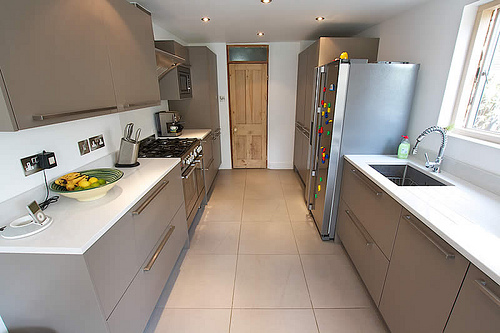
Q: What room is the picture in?
A: It is at the kitchen.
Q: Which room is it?
A: It is a kitchen.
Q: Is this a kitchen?
A: Yes, it is a kitchen.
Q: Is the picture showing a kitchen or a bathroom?
A: It is showing a kitchen.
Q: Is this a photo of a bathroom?
A: No, the picture is showing a kitchen.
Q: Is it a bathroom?
A: No, it is a kitchen.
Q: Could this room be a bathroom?
A: No, it is a kitchen.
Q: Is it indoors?
A: Yes, it is indoors.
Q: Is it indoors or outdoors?
A: It is indoors.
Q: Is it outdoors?
A: No, it is indoors.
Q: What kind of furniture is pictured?
A: The furniture is a drawer.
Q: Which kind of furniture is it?
A: The piece of furniture is a drawer.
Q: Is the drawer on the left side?
A: Yes, the drawer is on the left of the image.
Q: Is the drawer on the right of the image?
A: No, the drawer is on the left of the image.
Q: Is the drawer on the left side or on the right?
A: The drawer is on the left of the image.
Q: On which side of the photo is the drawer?
A: The drawer is on the left of the image.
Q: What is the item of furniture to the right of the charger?
A: The piece of furniture is a drawer.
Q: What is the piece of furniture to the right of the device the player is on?
A: The piece of furniture is a drawer.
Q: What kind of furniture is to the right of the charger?
A: The piece of furniture is a drawer.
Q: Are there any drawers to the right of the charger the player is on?
A: Yes, there is a drawer to the right of the charger.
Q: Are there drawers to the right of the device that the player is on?
A: Yes, there is a drawer to the right of the charger.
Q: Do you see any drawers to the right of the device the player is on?
A: Yes, there is a drawer to the right of the charger.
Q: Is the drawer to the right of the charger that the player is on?
A: Yes, the drawer is to the right of the charger.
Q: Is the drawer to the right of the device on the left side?
A: Yes, the drawer is to the right of the charger.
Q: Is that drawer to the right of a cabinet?
A: No, the drawer is to the right of the charger.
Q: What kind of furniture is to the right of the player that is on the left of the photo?
A: The piece of furniture is a drawer.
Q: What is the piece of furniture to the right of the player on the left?
A: The piece of furniture is a drawer.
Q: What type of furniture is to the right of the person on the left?
A: The piece of furniture is a drawer.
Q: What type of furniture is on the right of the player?
A: The piece of furniture is a drawer.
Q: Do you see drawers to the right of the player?
A: Yes, there is a drawer to the right of the player.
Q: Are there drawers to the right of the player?
A: Yes, there is a drawer to the right of the player.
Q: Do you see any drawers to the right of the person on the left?
A: Yes, there is a drawer to the right of the player.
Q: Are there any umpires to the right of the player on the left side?
A: No, there is a drawer to the right of the player.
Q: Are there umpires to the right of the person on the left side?
A: No, there is a drawer to the right of the player.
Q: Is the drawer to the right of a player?
A: Yes, the drawer is to the right of a player.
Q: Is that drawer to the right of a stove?
A: No, the drawer is to the right of a player.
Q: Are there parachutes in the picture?
A: No, there are no parachutes.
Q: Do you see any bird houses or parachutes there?
A: No, there are no parachutes or bird houses.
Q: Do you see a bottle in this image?
A: Yes, there is a bottle.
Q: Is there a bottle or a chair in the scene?
A: Yes, there is a bottle.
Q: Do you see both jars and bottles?
A: No, there is a bottle but no jars.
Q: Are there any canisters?
A: No, there are no canisters.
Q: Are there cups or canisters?
A: No, there are no canisters or cups.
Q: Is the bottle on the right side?
A: Yes, the bottle is on the right of the image.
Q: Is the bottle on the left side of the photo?
A: No, the bottle is on the right of the image.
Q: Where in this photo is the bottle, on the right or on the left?
A: The bottle is on the right of the image.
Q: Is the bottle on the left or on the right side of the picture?
A: The bottle is on the right of the image.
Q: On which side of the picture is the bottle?
A: The bottle is on the right of the image.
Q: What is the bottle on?
A: The bottle is on the countertop.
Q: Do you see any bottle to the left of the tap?
A: Yes, there is a bottle to the left of the tap.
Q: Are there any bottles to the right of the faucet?
A: No, the bottle is to the left of the faucet.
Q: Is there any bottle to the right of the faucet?
A: No, the bottle is to the left of the faucet.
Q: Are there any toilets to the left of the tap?
A: No, there is a bottle to the left of the tap.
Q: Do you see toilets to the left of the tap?
A: No, there is a bottle to the left of the tap.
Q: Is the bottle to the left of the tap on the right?
A: Yes, the bottle is to the left of the tap.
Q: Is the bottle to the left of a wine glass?
A: No, the bottle is to the left of the tap.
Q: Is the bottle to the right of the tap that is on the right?
A: No, the bottle is to the left of the tap.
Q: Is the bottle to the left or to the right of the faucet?
A: The bottle is to the left of the faucet.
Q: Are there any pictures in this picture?
A: No, there are no pictures.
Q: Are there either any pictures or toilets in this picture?
A: No, there are no pictures or toilets.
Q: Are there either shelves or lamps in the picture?
A: No, there are no shelves or lamps.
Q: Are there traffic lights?
A: No, there are no traffic lights.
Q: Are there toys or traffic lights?
A: No, there are no traffic lights or toys.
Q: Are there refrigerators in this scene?
A: Yes, there is a refrigerator.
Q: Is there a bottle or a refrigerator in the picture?
A: Yes, there is a refrigerator.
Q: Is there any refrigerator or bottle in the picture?
A: Yes, there is a refrigerator.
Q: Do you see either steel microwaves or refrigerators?
A: Yes, there is a steel refrigerator.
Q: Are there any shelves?
A: No, there are no shelves.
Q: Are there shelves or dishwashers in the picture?
A: No, there are no shelves or dishwashers.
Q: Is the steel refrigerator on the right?
A: Yes, the refrigerator is on the right of the image.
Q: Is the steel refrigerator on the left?
A: No, the fridge is on the right of the image.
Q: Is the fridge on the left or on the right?
A: The fridge is on the right of the image.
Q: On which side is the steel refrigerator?
A: The refrigerator is on the right of the image.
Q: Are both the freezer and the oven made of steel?
A: Yes, both the freezer and the oven are made of steel.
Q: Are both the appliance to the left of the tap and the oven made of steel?
A: Yes, both the freezer and the oven are made of steel.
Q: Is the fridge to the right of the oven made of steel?
A: Yes, the refrigerator is made of steel.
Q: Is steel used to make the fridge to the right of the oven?
A: Yes, the refrigerator is made of steel.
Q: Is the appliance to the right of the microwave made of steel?
A: Yes, the refrigerator is made of steel.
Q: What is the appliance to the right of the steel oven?
A: The appliance is a refrigerator.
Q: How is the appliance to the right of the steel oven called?
A: The appliance is a refrigerator.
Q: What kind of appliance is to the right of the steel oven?
A: The appliance is a refrigerator.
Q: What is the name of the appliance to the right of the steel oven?
A: The appliance is a refrigerator.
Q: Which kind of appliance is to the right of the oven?
A: The appliance is a refrigerator.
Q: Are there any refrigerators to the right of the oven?
A: Yes, there is a refrigerator to the right of the oven.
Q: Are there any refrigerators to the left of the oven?
A: No, the refrigerator is to the right of the oven.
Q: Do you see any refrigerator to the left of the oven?
A: No, the refrigerator is to the right of the oven.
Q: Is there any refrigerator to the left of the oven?
A: No, the refrigerator is to the right of the oven.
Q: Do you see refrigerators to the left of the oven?
A: No, the refrigerator is to the right of the oven.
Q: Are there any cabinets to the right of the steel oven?
A: No, there is a refrigerator to the right of the oven.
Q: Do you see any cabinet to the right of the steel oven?
A: No, there is a refrigerator to the right of the oven.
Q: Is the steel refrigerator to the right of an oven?
A: Yes, the freezer is to the right of an oven.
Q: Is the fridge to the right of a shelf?
A: No, the fridge is to the right of an oven.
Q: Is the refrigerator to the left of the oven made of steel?
A: No, the refrigerator is to the right of the oven.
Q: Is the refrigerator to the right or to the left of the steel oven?
A: The refrigerator is to the right of the oven.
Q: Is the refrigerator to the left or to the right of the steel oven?
A: The refrigerator is to the right of the oven.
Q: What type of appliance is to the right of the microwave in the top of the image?
A: The appliance is a refrigerator.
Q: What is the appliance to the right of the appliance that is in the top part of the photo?
A: The appliance is a refrigerator.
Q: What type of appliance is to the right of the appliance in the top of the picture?
A: The appliance is a refrigerator.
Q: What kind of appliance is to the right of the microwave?
A: The appliance is a refrigerator.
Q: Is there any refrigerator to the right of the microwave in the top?
A: Yes, there is a refrigerator to the right of the microwave.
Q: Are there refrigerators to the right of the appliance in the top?
A: Yes, there is a refrigerator to the right of the microwave.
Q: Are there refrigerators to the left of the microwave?
A: No, the refrigerator is to the right of the microwave.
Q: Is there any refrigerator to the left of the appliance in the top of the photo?
A: No, the refrigerator is to the right of the microwave.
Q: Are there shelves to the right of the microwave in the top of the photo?
A: No, there is a refrigerator to the right of the microwave.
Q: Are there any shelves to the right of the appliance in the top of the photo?
A: No, there is a refrigerator to the right of the microwave.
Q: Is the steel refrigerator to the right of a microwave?
A: Yes, the refrigerator is to the right of a microwave.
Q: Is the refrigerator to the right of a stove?
A: No, the refrigerator is to the right of a microwave.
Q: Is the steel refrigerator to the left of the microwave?
A: No, the freezer is to the right of the microwave.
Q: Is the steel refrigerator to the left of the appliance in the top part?
A: No, the freezer is to the right of the microwave.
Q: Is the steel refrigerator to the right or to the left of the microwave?
A: The freezer is to the right of the microwave.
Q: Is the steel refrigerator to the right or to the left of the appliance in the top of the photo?
A: The freezer is to the right of the microwave.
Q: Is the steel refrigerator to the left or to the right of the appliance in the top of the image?
A: The freezer is to the right of the microwave.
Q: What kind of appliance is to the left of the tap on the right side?
A: The appliance is a refrigerator.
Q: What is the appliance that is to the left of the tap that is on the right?
A: The appliance is a refrigerator.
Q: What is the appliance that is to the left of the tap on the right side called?
A: The appliance is a refrigerator.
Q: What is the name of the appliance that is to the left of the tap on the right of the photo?
A: The appliance is a refrigerator.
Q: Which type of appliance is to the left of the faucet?
A: The appliance is a refrigerator.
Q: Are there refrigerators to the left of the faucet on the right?
A: Yes, there is a refrigerator to the left of the faucet.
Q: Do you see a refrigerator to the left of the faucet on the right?
A: Yes, there is a refrigerator to the left of the faucet.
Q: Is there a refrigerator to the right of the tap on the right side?
A: No, the refrigerator is to the left of the faucet.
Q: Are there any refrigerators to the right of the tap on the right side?
A: No, the refrigerator is to the left of the faucet.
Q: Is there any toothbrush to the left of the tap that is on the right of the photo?
A: No, there is a refrigerator to the left of the faucet.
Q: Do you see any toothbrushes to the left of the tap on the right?
A: No, there is a refrigerator to the left of the faucet.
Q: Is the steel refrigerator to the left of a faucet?
A: Yes, the refrigerator is to the left of a faucet.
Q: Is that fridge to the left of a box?
A: No, the fridge is to the left of a faucet.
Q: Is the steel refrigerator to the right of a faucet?
A: No, the fridge is to the left of a faucet.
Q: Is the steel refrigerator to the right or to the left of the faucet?
A: The fridge is to the left of the faucet.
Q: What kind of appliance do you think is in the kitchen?
A: The appliance is a refrigerator.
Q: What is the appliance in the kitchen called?
A: The appliance is a refrigerator.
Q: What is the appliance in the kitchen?
A: The appliance is a refrigerator.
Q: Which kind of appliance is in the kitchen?
A: The appliance is a refrigerator.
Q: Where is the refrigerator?
A: The refrigerator is in the kitchen.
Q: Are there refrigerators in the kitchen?
A: Yes, there is a refrigerator in the kitchen.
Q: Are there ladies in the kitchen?
A: No, there is a refrigerator in the kitchen.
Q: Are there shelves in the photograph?
A: No, there are no shelves.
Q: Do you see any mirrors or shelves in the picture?
A: No, there are no shelves or mirrors.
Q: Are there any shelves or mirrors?
A: No, there are no shelves or mirrors.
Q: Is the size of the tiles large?
A: Yes, the tiles are large.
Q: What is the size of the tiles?
A: The tiles are large.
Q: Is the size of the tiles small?
A: No, the tiles are large.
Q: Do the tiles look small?
A: No, the tiles are large.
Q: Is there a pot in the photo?
A: No, there are no pots.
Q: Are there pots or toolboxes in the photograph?
A: No, there are no pots or toolboxes.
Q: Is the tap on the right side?
A: Yes, the tap is on the right of the image.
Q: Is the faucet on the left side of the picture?
A: No, the faucet is on the right of the image.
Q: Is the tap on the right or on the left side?
A: The tap is on the right of the image.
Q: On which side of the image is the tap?
A: The tap is on the right of the image.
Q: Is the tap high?
A: Yes, the tap is high.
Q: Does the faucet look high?
A: Yes, the faucet is high.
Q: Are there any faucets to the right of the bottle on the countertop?
A: Yes, there is a faucet to the right of the bottle.